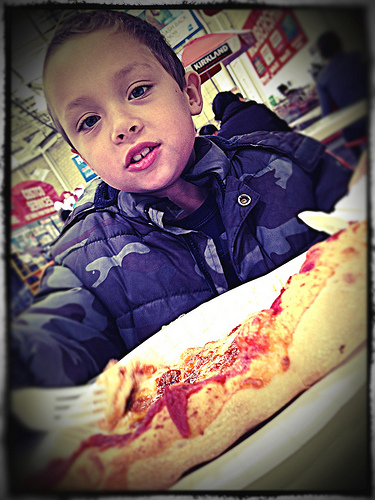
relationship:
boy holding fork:
[10, 12, 292, 367] [18, 376, 93, 427]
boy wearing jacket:
[10, 12, 292, 367] [45, 176, 316, 331]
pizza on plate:
[97, 312, 374, 461] [30, 277, 375, 473]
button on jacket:
[234, 192, 258, 208] [45, 176, 316, 331]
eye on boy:
[126, 84, 158, 104] [10, 12, 292, 367]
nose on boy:
[110, 115, 142, 142] [10, 12, 292, 367]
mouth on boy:
[123, 140, 159, 171] [10, 12, 292, 367]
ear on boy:
[186, 73, 204, 118] [10, 12, 292, 367]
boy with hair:
[10, 12, 292, 367] [35, 12, 188, 150]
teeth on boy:
[130, 147, 153, 161] [10, 12, 292, 367]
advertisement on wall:
[242, 23, 293, 56] [160, 12, 372, 101]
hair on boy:
[52, 12, 208, 80] [10, 12, 292, 367]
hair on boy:
[35, 12, 188, 150] [10, 12, 292, 367]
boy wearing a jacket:
[10, 12, 292, 367] [45, 176, 316, 331]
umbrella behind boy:
[180, 34, 254, 74] [10, 12, 292, 367]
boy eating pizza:
[10, 12, 292, 367] [97, 312, 374, 461]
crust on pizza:
[296, 293, 355, 350] [97, 312, 374, 461]